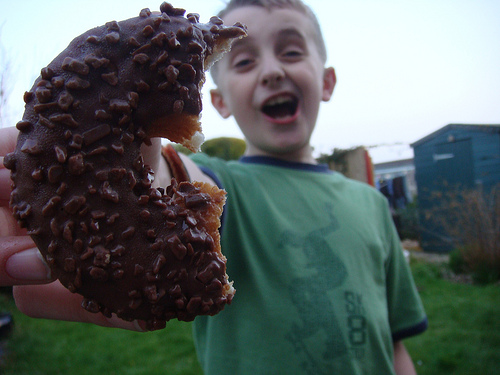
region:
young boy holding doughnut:
[2, 0, 429, 373]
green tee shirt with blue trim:
[192, 151, 432, 371]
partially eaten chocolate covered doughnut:
[13, 1, 242, 328]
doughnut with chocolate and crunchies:
[8, 2, 235, 327]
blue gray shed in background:
[408, 120, 499, 257]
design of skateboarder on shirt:
[271, 202, 356, 373]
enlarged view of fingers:
[3, 127, 162, 334]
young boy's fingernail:
[4, 243, 54, 283]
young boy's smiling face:
[208, 2, 335, 159]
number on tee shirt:
[343, 287, 369, 351]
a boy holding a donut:
[52, 13, 458, 373]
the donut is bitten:
[26, 11, 280, 323]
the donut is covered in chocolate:
[3, 6, 250, 328]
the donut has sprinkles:
[26, 5, 240, 332]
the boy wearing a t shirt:
[0, 2, 433, 374]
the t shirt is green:
[187, 139, 442, 374]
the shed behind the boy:
[406, 119, 498, 259]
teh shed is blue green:
[381, 110, 498, 267]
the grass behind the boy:
[30, 280, 487, 373]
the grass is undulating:
[36, 329, 483, 371]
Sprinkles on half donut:
[63, 58, 91, 92]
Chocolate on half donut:
[114, 205, 141, 217]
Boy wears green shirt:
[243, 165, 291, 235]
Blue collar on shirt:
[246, 152, 301, 168]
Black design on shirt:
[278, 204, 345, 341]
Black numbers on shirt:
[339, 282, 371, 352]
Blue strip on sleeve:
[396, 320, 430, 337]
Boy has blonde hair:
[251, 1, 291, 8]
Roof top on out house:
[407, 120, 498, 148]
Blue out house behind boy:
[398, 119, 498, 261]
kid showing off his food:
[40, 8, 420, 370]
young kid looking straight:
[58, 5, 458, 319]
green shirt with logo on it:
[185, 161, 399, 358]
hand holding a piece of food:
[1, 12, 198, 266]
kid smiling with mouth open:
[45, 10, 376, 185]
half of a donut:
[4, 25, 249, 317]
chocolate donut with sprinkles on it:
[1, 1, 271, 242]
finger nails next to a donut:
[25, 221, 77, 303]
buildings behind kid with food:
[378, 104, 495, 181]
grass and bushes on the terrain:
[412, 181, 480, 373]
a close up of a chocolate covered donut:
[8, 13, 248, 329]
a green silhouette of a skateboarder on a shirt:
[256, 207, 374, 354]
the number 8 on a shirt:
[347, 313, 366, 349]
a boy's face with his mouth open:
[212, 20, 352, 161]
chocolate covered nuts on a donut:
[90, 219, 188, 300]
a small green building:
[411, 127, 498, 260]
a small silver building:
[321, 140, 416, 196]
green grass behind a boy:
[28, 329, 130, 374]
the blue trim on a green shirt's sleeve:
[391, 317, 426, 341]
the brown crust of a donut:
[206, 187, 221, 224]